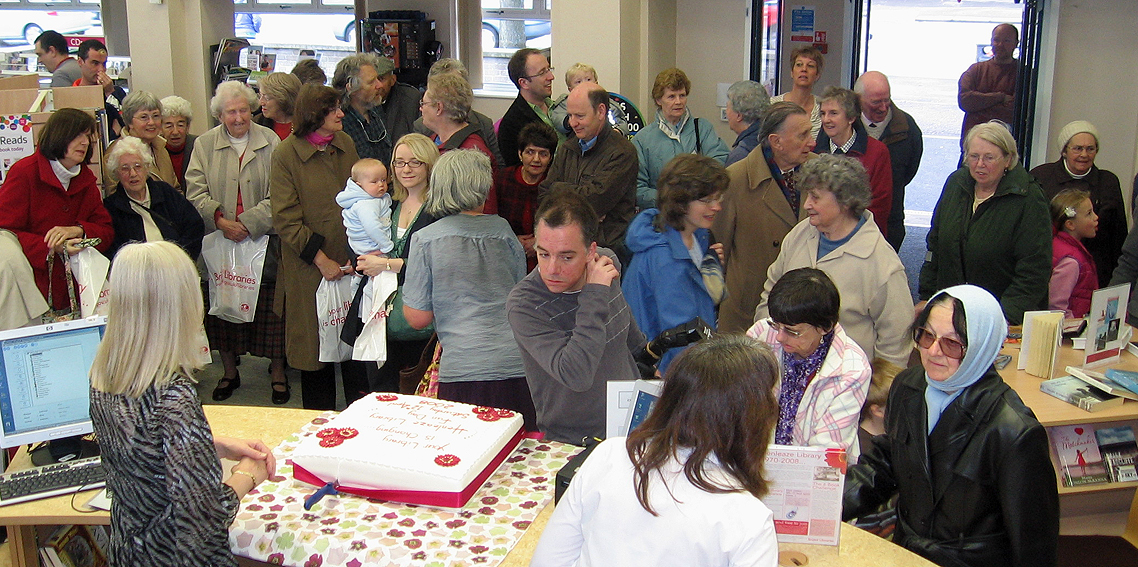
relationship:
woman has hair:
[84, 239, 237, 565] [89, 239, 205, 399]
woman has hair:
[84, 239, 237, 565] [90, 239, 216, 400]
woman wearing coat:
[3, 104, 118, 306] [1, 154, 112, 294]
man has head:
[533, 75, 644, 265] [558, 79, 609, 143]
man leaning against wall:
[955, 15, 1027, 145] [1025, 3, 1136, 222]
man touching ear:
[508, 202, 638, 439] [585, 237, 595, 263]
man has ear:
[508, 202, 638, 439] [585, 237, 595, 263]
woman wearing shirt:
[529, 332, 789, 565] [529, 435, 781, 565]